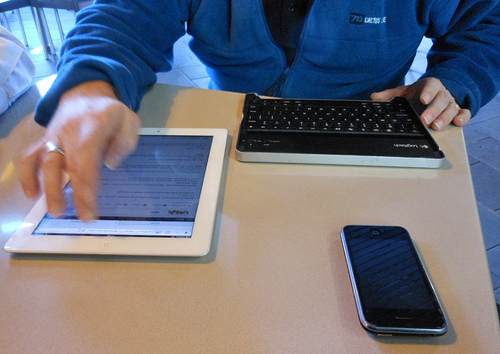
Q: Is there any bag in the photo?
A: Yes, there is a bag.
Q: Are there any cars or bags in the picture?
A: Yes, there is a bag.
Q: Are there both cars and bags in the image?
A: No, there is a bag but no cars.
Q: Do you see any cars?
A: No, there are no cars.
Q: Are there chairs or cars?
A: No, there are no cars or chairs.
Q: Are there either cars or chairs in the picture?
A: No, there are no cars or chairs.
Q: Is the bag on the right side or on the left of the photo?
A: The bag is on the left of the image.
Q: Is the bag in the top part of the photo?
A: Yes, the bag is in the top of the image.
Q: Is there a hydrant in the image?
A: No, there are no fire hydrants.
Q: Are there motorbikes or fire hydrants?
A: No, there are no fire hydrants or motorbikes.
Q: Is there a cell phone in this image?
A: Yes, there is a cell phone.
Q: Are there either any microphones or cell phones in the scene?
A: Yes, there is a cell phone.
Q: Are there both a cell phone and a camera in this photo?
A: No, there is a cell phone but no cameras.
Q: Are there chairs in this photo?
A: No, there are no chairs.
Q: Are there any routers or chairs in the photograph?
A: No, there are no chairs or routers.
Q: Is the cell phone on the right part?
A: Yes, the cell phone is on the right of the image.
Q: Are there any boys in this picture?
A: No, there are no boys.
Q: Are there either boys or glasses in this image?
A: No, there are no boys or glasses.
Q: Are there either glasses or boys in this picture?
A: No, there are no boys or glasses.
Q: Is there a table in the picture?
A: Yes, there is a table.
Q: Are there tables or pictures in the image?
A: Yes, there is a table.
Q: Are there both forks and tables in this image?
A: No, there is a table but no forks.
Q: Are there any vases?
A: No, there are no vases.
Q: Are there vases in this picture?
A: No, there are no vases.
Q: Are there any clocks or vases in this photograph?
A: No, there are no vases or clocks.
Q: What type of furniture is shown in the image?
A: The furniture is a table.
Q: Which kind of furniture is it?
A: The piece of furniture is a table.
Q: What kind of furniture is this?
A: This is a table.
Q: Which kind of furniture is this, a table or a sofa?
A: This is a table.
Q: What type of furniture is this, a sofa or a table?
A: This is a table.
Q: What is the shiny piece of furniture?
A: The piece of furniture is a table.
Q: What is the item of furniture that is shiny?
A: The piece of furniture is a table.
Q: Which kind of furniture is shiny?
A: The furniture is a table.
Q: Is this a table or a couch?
A: This is a table.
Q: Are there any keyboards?
A: Yes, there is a keyboard.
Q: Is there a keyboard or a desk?
A: Yes, there is a keyboard.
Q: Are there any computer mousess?
A: No, there are no computer mousess.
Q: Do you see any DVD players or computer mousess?
A: No, there are no computer mousess or DVD players.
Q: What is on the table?
A: The keyboard is on the table.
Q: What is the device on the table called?
A: The device is a keyboard.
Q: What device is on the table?
A: The device is a keyboard.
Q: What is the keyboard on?
A: The keyboard is on the table.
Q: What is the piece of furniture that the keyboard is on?
A: The piece of furniture is a table.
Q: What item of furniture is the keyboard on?
A: The keyboard is on the table.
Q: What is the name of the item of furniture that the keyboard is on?
A: The piece of furniture is a table.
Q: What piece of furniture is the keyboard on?
A: The keyboard is on the table.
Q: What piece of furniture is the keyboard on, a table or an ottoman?
A: The keyboard is on a table.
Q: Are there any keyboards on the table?
A: Yes, there is a keyboard on the table.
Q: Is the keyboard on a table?
A: Yes, the keyboard is on a table.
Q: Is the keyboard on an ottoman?
A: No, the keyboard is on a table.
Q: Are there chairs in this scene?
A: No, there are no chairs.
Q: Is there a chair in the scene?
A: No, there are no chairs.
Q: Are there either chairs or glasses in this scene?
A: No, there are no chairs or glasses.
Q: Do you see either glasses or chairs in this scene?
A: No, there are no chairs or glasses.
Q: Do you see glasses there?
A: No, there are no glasses.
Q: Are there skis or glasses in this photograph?
A: No, there are no glasses or skis.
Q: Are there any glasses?
A: No, there are no glasses.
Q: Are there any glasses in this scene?
A: No, there are no glasses.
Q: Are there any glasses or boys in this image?
A: No, there are no glasses or boys.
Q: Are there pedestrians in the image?
A: No, there are no pedestrians.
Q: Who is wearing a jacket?
A: The man is wearing a jacket.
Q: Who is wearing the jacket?
A: The man is wearing a jacket.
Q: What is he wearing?
A: The man is wearing a jacket.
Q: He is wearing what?
A: The man is wearing a jacket.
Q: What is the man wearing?
A: The man is wearing a jacket.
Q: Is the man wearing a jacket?
A: Yes, the man is wearing a jacket.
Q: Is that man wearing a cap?
A: No, the man is wearing a jacket.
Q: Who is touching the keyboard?
A: The man is touching the keyboard.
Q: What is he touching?
A: The man is touching the keyboard.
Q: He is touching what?
A: The man is touching the keyboard.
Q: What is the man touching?
A: The man is touching the keyboard.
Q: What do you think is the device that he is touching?
A: The device is a keyboard.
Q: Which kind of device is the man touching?
A: The man is touching the keyboard.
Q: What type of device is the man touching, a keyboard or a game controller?
A: The man is touching a keyboard.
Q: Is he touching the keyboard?
A: Yes, the man is touching the keyboard.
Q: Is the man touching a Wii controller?
A: No, the man is touching the keyboard.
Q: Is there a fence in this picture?
A: No, there are no fences.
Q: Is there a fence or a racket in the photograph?
A: No, there are no fences or rackets.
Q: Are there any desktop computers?
A: No, there are no desktop computers.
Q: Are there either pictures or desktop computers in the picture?
A: No, there are no desktop computers or pictures.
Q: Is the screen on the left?
A: Yes, the screen is on the left of the image.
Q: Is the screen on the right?
A: No, the screen is on the left of the image.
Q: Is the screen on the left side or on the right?
A: The screen is on the left of the image.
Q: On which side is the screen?
A: The screen is on the left of the image.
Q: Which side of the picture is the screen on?
A: The screen is on the left of the image.